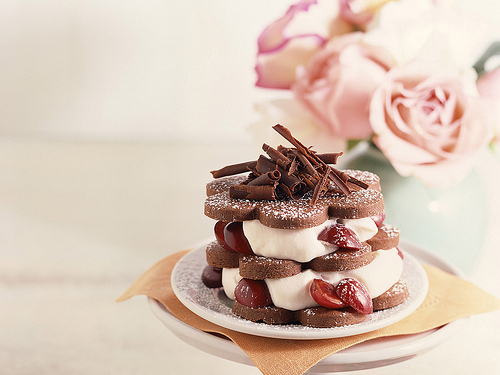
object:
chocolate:
[305, 165, 333, 205]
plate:
[146, 236, 469, 373]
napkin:
[114, 245, 500, 375]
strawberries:
[307, 277, 346, 308]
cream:
[219, 248, 401, 312]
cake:
[200, 124, 408, 328]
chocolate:
[227, 184, 275, 199]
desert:
[184, 154, 410, 354]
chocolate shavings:
[209, 161, 254, 181]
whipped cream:
[241, 218, 379, 264]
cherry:
[317, 224, 363, 251]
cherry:
[232, 278, 274, 308]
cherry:
[307, 278, 347, 308]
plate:
[170, 243, 429, 340]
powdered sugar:
[205, 168, 377, 219]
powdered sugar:
[240, 254, 292, 270]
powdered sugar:
[324, 227, 360, 247]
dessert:
[200, 122, 408, 329]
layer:
[204, 251, 407, 327]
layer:
[205, 218, 400, 278]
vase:
[340, 141, 489, 275]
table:
[0, 0, 499, 374]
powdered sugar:
[172, 242, 267, 327]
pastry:
[202, 167, 386, 230]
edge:
[251, 0, 328, 91]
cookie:
[203, 224, 401, 280]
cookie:
[231, 282, 410, 330]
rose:
[365, 60, 497, 191]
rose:
[287, 30, 396, 142]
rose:
[254, 0, 378, 92]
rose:
[342, 0, 384, 31]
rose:
[359, 0, 474, 70]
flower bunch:
[289, 0, 499, 191]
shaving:
[267, 123, 327, 169]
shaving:
[225, 183, 276, 201]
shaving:
[243, 170, 281, 186]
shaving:
[308, 162, 332, 208]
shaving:
[254, 153, 300, 188]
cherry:
[333, 276, 373, 317]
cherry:
[221, 222, 253, 258]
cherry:
[201, 265, 223, 289]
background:
[0, 0, 499, 374]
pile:
[210, 124, 370, 206]